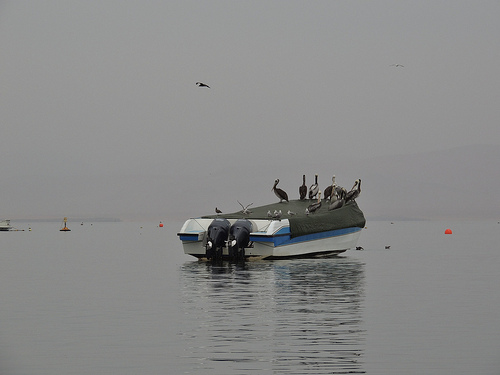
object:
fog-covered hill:
[198, 199, 365, 239]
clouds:
[4, 3, 499, 228]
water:
[3, 196, 493, 372]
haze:
[1, 0, 499, 221]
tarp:
[190, 199, 365, 239]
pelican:
[346, 179, 363, 204]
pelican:
[324, 175, 336, 200]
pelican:
[308, 174, 319, 200]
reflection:
[180, 251, 362, 374]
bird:
[194, 81, 210, 89]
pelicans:
[328, 190, 346, 212]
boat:
[176, 199, 365, 261]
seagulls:
[237, 200, 255, 214]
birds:
[306, 190, 322, 215]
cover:
[200, 199, 365, 240]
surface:
[11, 281, 497, 364]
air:
[10, 9, 490, 155]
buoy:
[60, 215, 72, 231]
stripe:
[265, 220, 356, 240]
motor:
[207, 219, 250, 262]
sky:
[7, 13, 499, 160]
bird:
[271, 178, 290, 203]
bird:
[298, 175, 307, 200]